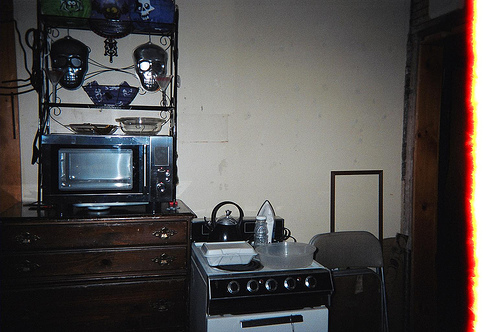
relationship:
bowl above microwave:
[80, 80, 140, 108] [40, 131, 177, 213]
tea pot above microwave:
[201, 201, 245, 240] [40, 131, 177, 213]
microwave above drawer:
[40, 131, 177, 213] [2, 196, 200, 329]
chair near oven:
[308, 230, 395, 331] [188, 213, 335, 331]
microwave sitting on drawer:
[40, 131, 177, 213] [2, 196, 200, 329]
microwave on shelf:
[40, 131, 177, 213] [45, 202, 174, 206]